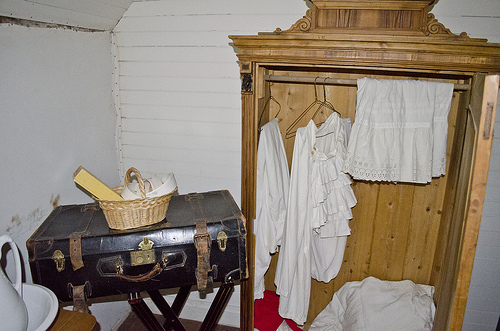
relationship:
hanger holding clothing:
[255, 66, 348, 144] [252, 70, 462, 329]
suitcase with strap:
[27, 190, 249, 302] [61, 214, 88, 274]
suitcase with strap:
[27, 190, 249, 302] [183, 196, 220, 293]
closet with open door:
[225, 0, 491, 330] [241, 59, 491, 313]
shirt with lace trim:
[272, 113, 358, 325] [309, 149, 359, 238]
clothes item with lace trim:
[274, 111, 360, 325] [309, 149, 359, 238]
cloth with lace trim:
[343, 68, 455, 190] [344, 157, 446, 182]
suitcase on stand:
[27, 190, 249, 302] [112, 287, 247, 328]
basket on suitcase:
[92, 169, 178, 226] [37, 200, 241, 293]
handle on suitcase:
[111, 263, 161, 283] [27, 190, 249, 302]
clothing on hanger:
[252, 70, 462, 329] [255, 66, 348, 144]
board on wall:
[122, 116, 239, 140] [112, 0, 311, 195]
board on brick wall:
[114, 12, 171, 63] [114, 0, 499, 330]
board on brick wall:
[122, 116, 239, 140] [114, 0, 499, 330]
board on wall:
[471, 290, 493, 326] [470, 247, 497, 307]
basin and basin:
[1, 231, 62, 329] [1, 231, 40, 329]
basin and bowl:
[1, 231, 40, 329] [13, 280, 67, 329]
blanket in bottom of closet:
[314, 270, 441, 329] [225, 0, 491, 330]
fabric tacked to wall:
[11, 31, 121, 278] [1, 14, 130, 329]